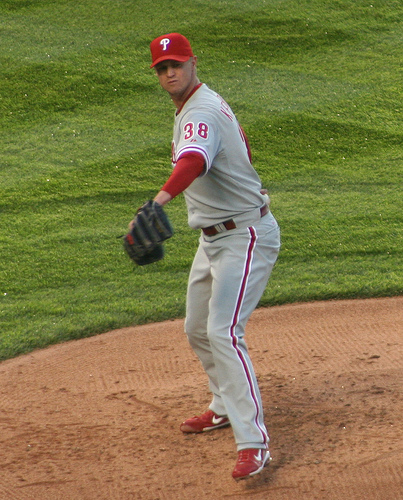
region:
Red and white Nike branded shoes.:
[177, 403, 274, 481]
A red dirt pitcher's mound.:
[1, 293, 401, 497]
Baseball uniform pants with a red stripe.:
[183, 196, 283, 446]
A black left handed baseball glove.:
[121, 198, 174, 265]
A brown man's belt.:
[200, 201, 275, 237]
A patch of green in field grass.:
[268, 34, 387, 193]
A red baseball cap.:
[147, 31, 195, 68]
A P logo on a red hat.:
[157, 36, 170, 51]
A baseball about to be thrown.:
[259, 188, 275, 207]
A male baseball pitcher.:
[117, 29, 286, 483]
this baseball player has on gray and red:
[93, 36, 285, 301]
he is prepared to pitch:
[101, 33, 296, 275]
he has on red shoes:
[186, 390, 342, 479]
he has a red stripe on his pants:
[204, 224, 289, 447]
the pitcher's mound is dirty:
[67, 368, 381, 485]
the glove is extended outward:
[107, 175, 215, 279]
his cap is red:
[132, 28, 201, 93]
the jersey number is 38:
[164, 114, 241, 175]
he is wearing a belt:
[186, 193, 302, 239]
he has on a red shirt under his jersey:
[138, 125, 216, 203]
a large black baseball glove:
[121, 202, 179, 267]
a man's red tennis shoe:
[228, 446, 269, 479]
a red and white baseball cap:
[148, 32, 191, 69]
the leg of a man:
[202, 214, 282, 451]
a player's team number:
[181, 120, 214, 142]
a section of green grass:
[0, 0, 401, 360]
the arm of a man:
[150, 113, 217, 201]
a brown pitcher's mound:
[0, 294, 400, 498]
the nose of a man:
[165, 62, 177, 78]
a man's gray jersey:
[170, 87, 270, 228]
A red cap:
[141, 21, 194, 67]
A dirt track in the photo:
[76, 360, 172, 457]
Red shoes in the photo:
[171, 405, 278, 476]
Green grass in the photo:
[258, 59, 358, 169]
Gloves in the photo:
[119, 201, 178, 263]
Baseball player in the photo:
[132, 25, 274, 494]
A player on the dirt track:
[134, 21, 274, 476]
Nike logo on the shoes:
[247, 448, 267, 462]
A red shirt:
[162, 159, 199, 194]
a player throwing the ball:
[97, 11, 290, 484]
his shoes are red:
[176, 410, 276, 482]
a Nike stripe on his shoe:
[251, 444, 263, 461]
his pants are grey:
[172, 219, 273, 488]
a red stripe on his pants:
[228, 225, 267, 450]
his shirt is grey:
[149, 87, 267, 233]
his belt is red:
[194, 192, 280, 246]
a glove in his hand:
[107, 195, 177, 274]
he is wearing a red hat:
[143, 31, 201, 67]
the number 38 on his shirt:
[175, 113, 215, 146]